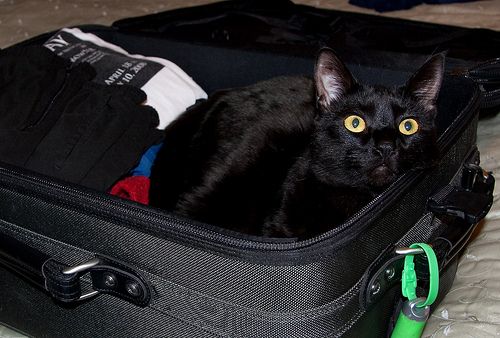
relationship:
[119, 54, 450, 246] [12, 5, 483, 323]
cat staring in suitcase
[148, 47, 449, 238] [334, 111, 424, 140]
cat has eyes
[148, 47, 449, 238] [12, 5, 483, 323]
cat in suitcase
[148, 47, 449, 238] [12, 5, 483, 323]
cat sitting and looking in suitcase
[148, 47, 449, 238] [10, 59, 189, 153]
cat sits on top of clothes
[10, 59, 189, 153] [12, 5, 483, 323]
clothes in suitcase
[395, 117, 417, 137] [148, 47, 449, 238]
eye of cat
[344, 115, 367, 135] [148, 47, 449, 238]
cat eyes of cat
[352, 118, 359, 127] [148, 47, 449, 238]
black pupil of cat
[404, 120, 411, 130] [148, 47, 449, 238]
black pupil of cat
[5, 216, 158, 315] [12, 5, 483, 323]
handle of suitcase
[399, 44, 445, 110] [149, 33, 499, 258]
ear of cat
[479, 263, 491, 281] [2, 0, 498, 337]
part of mattress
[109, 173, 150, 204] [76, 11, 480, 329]
clothing in suitcase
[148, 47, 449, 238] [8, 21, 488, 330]
cat in suit case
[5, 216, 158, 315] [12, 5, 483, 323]
handle on suitcase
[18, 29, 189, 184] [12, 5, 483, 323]
clothing in suitcase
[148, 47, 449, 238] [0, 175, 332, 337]
cat in suitcase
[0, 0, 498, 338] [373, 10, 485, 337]
suit case laying on bed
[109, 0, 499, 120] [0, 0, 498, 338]
lid of suit case